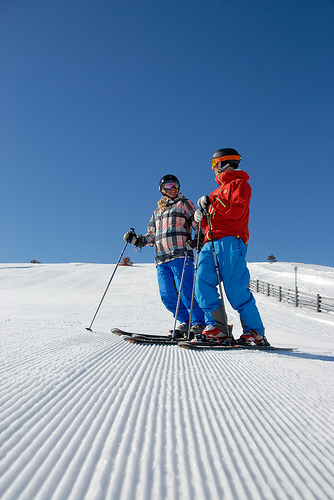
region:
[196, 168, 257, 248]
WARM RED JACKET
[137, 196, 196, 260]
COLORFUL PLAID JACKET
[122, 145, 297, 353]
TWO PEOPLE STANDING WITH SKIS ON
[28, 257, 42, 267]
SMALL BUILDING ON THE TOP OF THE HILL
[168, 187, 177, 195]
SKIER LOOKS HAPPY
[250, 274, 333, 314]
FENCING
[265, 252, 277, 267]
ONE TREE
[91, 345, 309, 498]
LINES IN THE SNOW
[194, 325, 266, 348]
RED AND WHITE SKI BOOTS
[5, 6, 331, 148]
SUNNY DAY WITH NO CLOUDS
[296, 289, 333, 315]
Fence on the right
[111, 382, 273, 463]
Snow is on the ground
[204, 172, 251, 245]
Red jacket with a yellow zipper.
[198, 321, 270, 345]
Red and white boots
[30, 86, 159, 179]
A blue sky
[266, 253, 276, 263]
A tree on the hill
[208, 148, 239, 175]
A black helmet with orange goggles.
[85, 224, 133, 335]
A ski pole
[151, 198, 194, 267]
A striped jacket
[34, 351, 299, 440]
The snow has a ridge pattern.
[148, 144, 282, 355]
Friends stop discuss plans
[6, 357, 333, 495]
Machine prepared now slope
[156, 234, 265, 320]
Both wear blue ski pants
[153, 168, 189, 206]
Safety helmet snow goggles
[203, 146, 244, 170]
Red strap holds goggles head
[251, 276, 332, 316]
Wooden fence along slope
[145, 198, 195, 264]
Colorful plaid jacket warm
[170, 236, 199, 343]
Ski poles needed balance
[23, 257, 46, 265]
Small building horizon left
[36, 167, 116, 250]
Deep blue sky clear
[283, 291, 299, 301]
section of a fence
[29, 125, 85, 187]
part of a blue sky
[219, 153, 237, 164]
section of a helmet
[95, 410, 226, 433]
part of white snow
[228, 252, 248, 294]
section of a blue track suite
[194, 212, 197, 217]
section of white gloves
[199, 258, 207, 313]
right leg of a boy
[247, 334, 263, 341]
part of skating shoes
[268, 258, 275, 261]
a tree in the background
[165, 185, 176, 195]
face of a skater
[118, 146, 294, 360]
two skiers talking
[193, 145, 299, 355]
skier in red jacket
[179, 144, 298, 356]
skier holding ski poles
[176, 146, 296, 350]
skier wearing blue ski pants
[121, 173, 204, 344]
snow skier in plaid jacket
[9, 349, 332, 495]
plowed field of snow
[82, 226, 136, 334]
ski pole held by skier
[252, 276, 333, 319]
fence around snowy field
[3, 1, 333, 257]
clear blue sky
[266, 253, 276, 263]
tree on hill in distance